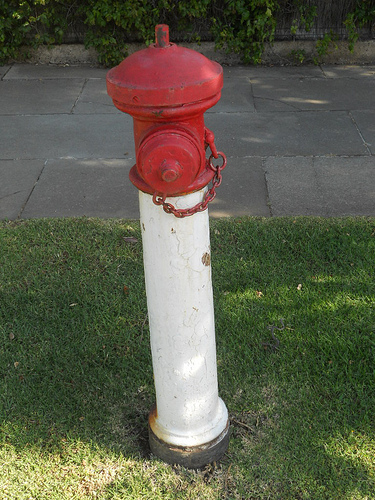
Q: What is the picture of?
A: A water hydrant.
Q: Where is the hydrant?
A: Near a walkway.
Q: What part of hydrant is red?
A: Top.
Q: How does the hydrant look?
A: It has white pole and red top.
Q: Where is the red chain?
A: At the joint of white pole and red hydrant.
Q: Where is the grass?
A: Under and around the hydrant.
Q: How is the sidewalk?
A: Grey and paved.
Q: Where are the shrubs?
A: At the far edge of the sidewalk.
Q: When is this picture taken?
A: During daytime.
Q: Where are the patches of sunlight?
A: On the green grass near the base of the white pole.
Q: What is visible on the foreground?
A: A fire hydrant.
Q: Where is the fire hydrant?
A: On grass.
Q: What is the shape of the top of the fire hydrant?
A: Round.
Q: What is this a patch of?
A: Green grass.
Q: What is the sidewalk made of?
A: Cement.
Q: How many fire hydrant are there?
A: One.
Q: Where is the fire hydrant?
A: By the sidewalk.